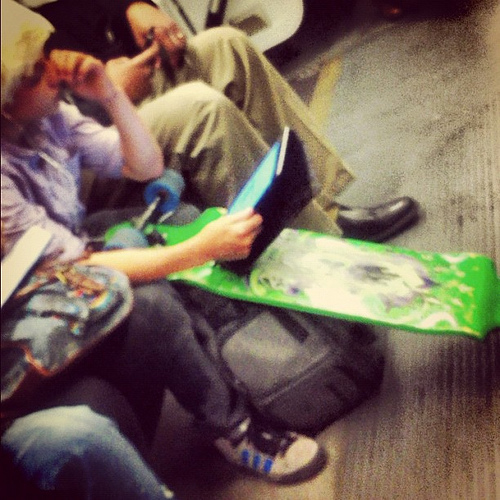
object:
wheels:
[145, 170, 186, 213]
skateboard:
[107, 167, 499, 342]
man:
[16, 0, 421, 243]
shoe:
[325, 195, 423, 242]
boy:
[0, 0, 329, 487]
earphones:
[4, 99, 14, 124]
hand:
[203, 207, 263, 264]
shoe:
[204, 413, 329, 485]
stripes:
[237, 445, 273, 477]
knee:
[32, 404, 114, 467]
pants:
[0, 401, 184, 497]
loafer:
[333, 194, 421, 242]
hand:
[127, 2, 191, 70]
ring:
[173, 28, 187, 40]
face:
[15, 49, 61, 124]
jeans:
[113, 285, 251, 440]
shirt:
[2, 98, 121, 257]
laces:
[233, 412, 295, 458]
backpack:
[203, 305, 386, 437]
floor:
[322, 49, 444, 167]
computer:
[227, 125, 322, 280]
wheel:
[142, 170, 188, 217]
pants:
[97, 24, 356, 240]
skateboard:
[2, 263, 133, 409]